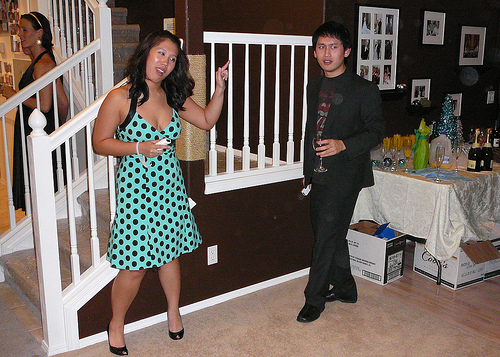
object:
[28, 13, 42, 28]
headband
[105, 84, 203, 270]
dress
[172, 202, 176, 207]
polka dot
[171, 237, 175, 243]
polka dot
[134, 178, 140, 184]
polka dot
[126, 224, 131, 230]
polka dot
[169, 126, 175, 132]
polka dot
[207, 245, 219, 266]
panel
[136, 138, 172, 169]
controller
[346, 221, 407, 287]
cardboard box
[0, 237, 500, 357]
floor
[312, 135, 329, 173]
glass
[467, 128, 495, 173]
bottles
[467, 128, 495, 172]
champagne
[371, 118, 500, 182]
refreshments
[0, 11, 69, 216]
girl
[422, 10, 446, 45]
picture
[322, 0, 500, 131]
wall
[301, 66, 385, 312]
suit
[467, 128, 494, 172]
item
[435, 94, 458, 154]
item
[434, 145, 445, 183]
item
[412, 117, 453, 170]
item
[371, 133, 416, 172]
item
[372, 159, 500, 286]
table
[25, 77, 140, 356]
railing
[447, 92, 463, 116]
picture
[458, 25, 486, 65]
picture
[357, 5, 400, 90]
picture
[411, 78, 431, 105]
picture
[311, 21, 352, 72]
head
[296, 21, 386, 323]
boy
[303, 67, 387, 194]
blazer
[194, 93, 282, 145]
wall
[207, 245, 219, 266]
outlet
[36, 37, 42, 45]
earring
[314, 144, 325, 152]
wine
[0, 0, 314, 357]
stairs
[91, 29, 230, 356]
girl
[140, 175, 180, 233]
dots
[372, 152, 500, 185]
table top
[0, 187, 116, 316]
steps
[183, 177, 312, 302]
wall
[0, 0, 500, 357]
basement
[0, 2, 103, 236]
background